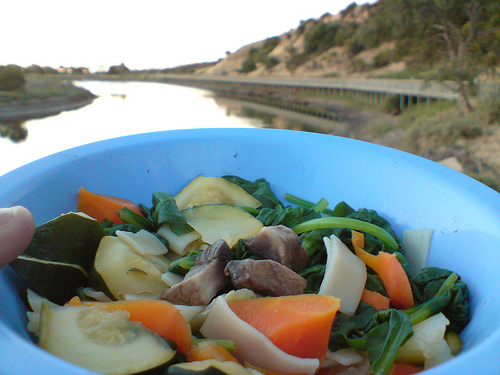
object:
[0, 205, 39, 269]
person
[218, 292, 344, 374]
carrot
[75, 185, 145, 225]
carrot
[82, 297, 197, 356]
carrot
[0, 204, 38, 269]
thumb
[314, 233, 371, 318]
cheese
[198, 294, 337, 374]
cheese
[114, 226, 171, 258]
cheese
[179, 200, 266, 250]
cucumber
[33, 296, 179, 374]
cucumber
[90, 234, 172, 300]
cucumber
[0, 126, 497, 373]
bowl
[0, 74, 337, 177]
river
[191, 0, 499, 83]
hill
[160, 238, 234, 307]
mushrooms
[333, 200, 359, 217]
greens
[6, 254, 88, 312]
food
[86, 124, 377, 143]
edge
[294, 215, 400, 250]
spinach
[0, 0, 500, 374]
background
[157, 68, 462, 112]
rail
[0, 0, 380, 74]
sky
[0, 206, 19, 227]
fingernail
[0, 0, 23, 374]
left